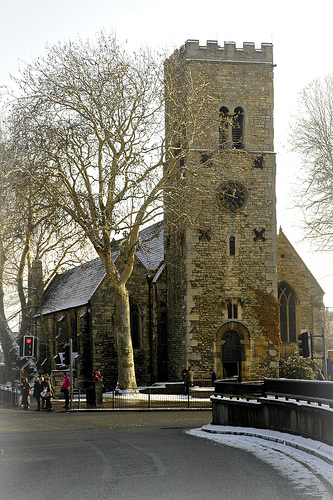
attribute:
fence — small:
[207, 372, 331, 448]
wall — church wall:
[182, 40, 278, 371]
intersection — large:
[1, 404, 332, 498]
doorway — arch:
[213, 340, 248, 382]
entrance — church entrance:
[210, 314, 258, 392]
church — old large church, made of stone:
[27, 43, 291, 425]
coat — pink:
[59, 374, 69, 388]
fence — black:
[110, 382, 189, 407]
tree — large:
[5, 24, 194, 413]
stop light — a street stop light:
[19, 336, 38, 355]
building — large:
[121, 155, 290, 377]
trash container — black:
[83, 376, 105, 408]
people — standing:
[15, 369, 104, 414]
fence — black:
[0, 385, 215, 412]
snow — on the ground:
[203, 421, 322, 476]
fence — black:
[2, 387, 215, 406]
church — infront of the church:
[27, 39, 331, 382]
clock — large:
[216, 178, 248, 212]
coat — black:
[210, 372, 216, 384]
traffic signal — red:
[18, 333, 37, 358]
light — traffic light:
[21, 326, 50, 358]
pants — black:
[63, 389, 69, 413]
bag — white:
[38, 380, 51, 399]